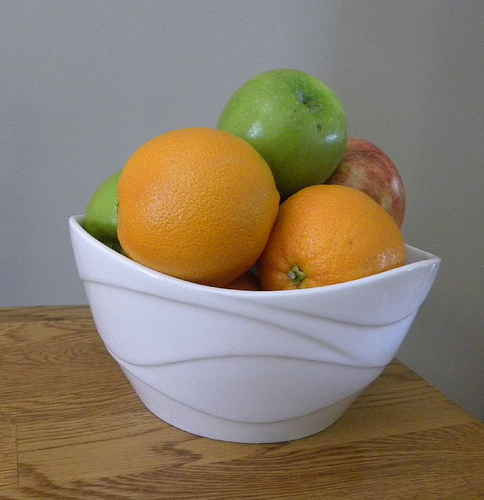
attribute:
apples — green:
[232, 65, 404, 208]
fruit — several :
[109, 73, 415, 290]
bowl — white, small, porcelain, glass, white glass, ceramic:
[72, 196, 434, 454]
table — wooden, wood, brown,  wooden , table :
[2, 285, 480, 498]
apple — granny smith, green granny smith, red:
[229, 62, 353, 189]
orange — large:
[121, 123, 278, 285]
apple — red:
[346, 131, 421, 237]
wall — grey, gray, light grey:
[9, 13, 168, 146]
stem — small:
[280, 259, 314, 288]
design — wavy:
[74, 268, 409, 434]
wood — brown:
[21, 408, 132, 480]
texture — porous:
[169, 175, 242, 243]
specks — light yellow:
[277, 81, 296, 115]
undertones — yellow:
[353, 158, 396, 198]